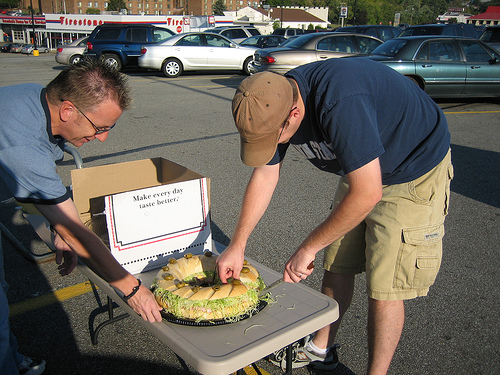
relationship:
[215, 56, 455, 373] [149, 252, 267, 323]
man cutting a sandwich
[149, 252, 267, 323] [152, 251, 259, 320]
sandwich with bread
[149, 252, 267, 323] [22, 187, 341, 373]
sandwich on top of a table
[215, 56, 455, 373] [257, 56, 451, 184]
man wearing a t-shirt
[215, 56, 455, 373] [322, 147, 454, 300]
man wearing shorts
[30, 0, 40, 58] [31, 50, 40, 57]
pole with base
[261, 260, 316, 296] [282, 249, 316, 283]
knife in a hand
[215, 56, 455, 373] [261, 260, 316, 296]
person with a knife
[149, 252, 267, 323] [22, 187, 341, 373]
food on top of a table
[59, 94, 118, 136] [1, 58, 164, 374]
glasses on a person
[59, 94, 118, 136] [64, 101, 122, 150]
glasses on a face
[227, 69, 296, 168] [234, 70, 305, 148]
hat on top of a head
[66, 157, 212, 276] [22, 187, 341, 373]
box on top of a table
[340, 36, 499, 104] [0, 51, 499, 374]
vehicle in a lot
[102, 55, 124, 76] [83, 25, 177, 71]
rear wheel of a vehicle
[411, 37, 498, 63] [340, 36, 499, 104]
side windows on a vehicle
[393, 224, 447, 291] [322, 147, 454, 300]
pocket on shorts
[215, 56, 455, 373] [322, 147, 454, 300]
person wearing shorts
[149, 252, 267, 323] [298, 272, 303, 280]
sandwich shaped like a ring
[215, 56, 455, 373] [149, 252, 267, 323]
man cutting sandwich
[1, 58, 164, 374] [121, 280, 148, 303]
man wearing a bracelet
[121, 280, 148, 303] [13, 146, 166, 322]
bracelet on an arm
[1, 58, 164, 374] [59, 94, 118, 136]
man wearing glasses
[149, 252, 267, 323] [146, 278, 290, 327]
sandwich on top of a plate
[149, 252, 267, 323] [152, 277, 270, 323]
sandwich with lettuce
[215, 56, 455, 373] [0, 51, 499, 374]
man standing in a lot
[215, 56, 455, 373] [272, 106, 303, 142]
man wearing glasses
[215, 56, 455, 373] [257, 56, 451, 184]
man wearing shirt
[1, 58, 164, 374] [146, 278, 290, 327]
man holding tray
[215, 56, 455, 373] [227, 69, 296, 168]
man wearing a cap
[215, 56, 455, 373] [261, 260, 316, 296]
man holding knife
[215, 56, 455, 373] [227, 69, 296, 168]
man wearing a hat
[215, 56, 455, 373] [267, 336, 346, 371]
man wearing sneakers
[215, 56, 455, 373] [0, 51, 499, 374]
man in parking lot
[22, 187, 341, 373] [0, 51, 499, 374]
table in parking lot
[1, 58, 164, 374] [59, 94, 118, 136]
man with glasses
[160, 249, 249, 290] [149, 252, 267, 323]
olives on top of sandwich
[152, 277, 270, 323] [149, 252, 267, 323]
lettuce in sandwich